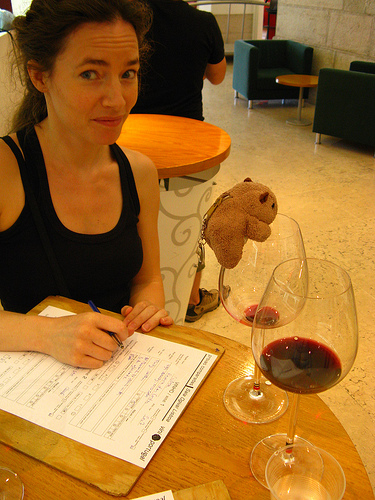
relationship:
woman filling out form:
[0, 0, 175, 371] [0, 303, 218, 469]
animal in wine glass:
[202, 176, 277, 269] [196, 200, 312, 329]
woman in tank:
[0, 0, 175, 371] [0, 133, 141, 309]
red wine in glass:
[243, 302, 280, 325] [251, 257, 358, 491]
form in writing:
[0, 303, 218, 469] [42, 344, 195, 433]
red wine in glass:
[259, 335, 342, 396] [251, 257, 358, 491]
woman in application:
[0, 0, 175, 371] [1, 304, 217, 467]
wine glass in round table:
[243, 256, 365, 477] [0, 292, 375, 500]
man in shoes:
[130, 0, 225, 122] [184, 288, 221, 323]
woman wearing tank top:
[3, 11, 193, 336] [1, 126, 163, 334]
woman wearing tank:
[0, 0, 175, 371] [0, 118, 146, 315]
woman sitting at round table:
[0, 0, 175, 371] [2, 292, 373, 499]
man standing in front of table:
[130, 0, 226, 122] [122, 103, 240, 335]